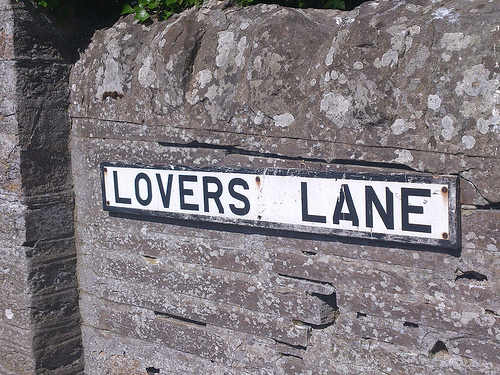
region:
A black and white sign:
[97, 161, 462, 253]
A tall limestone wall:
[0, 1, 497, 373]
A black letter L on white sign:
[111, 169, 133, 204]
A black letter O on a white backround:
[133, 171, 154, 207]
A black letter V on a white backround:
[153, 170, 174, 210]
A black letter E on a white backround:
[176, 172, 201, 213]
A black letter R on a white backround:
[201, 175, 225, 215]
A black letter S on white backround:
[225, 177, 252, 218]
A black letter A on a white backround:
[332, 181, 361, 227]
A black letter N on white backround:
[362, 182, 395, 231]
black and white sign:
[103, 166, 450, 245]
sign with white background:
[100, 150, 455, 250]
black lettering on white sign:
[110, 172, 442, 230]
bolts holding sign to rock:
[98, 162, 452, 241]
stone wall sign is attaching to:
[78, 10, 499, 374]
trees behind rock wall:
[113, 0, 348, 19]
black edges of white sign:
[94, 159, 461, 253]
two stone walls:
[5, 9, 498, 374]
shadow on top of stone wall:
[15, 10, 107, 75]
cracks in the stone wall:
[126, 234, 498, 374]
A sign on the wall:
[100, 162, 462, 253]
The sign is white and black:
[101, 162, 460, 252]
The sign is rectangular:
[99, 162, 461, 253]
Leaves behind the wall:
[123, 1, 177, 21]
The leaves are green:
[123, 1, 170, 23]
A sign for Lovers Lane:
[98, 163, 460, 250]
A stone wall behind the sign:
[3, 3, 495, 373]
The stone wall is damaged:
[2, 2, 499, 372]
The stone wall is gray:
[2, 2, 499, 374]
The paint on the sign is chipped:
[102, 164, 462, 252]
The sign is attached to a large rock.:
[53, 0, 498, 371]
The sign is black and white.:
[86, 148, 483, 261]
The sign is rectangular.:
[82, 140, 491, 265]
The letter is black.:
[107, 166, 133, 206]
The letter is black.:
[128, 170, 157, 209]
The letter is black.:
[153, 171, 177, 211]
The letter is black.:
[177, 169, 202, 211]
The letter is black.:
[198, 171, 225, 217]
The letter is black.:
[226, 175, 253, 217]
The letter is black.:
[358, 182, 396, 234]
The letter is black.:
[293, 178, 331, 227]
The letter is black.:
[328, 180, 363, 230]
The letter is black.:
[393, 183, 435, 235]